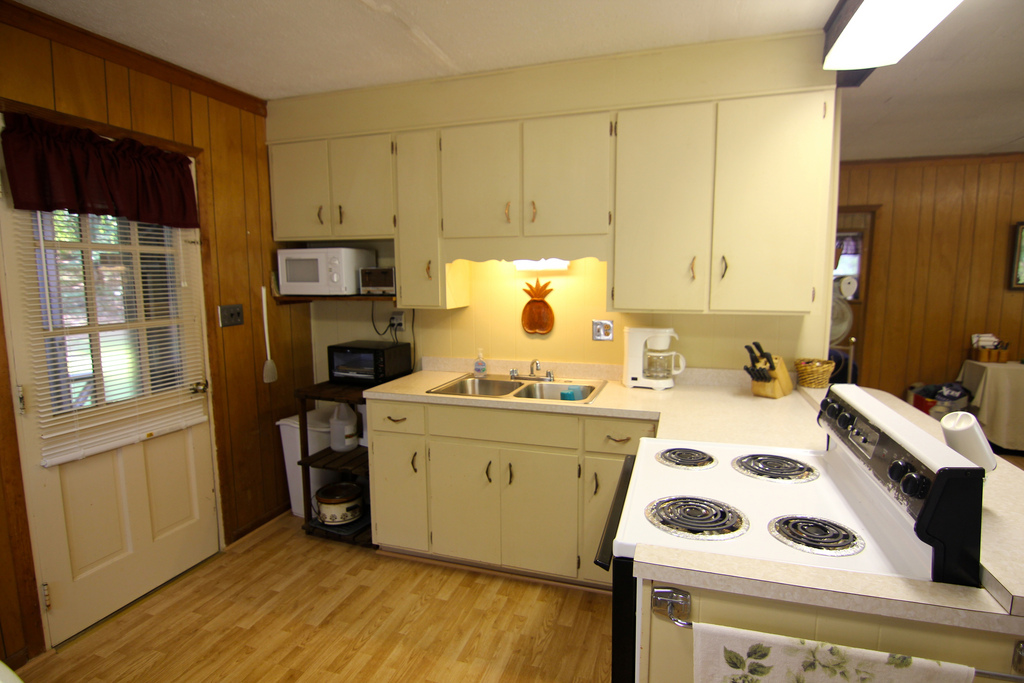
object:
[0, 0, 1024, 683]
kitchen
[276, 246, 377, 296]
microwave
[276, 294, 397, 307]
shelf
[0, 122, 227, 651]
door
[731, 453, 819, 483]
burner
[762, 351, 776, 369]
knives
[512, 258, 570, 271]
light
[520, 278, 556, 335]
ceramic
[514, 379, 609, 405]
sink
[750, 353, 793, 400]
block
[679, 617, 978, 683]
towel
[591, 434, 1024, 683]
oven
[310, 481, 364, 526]
crockpot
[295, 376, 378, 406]
shelf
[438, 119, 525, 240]
cabinet door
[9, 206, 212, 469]
blinds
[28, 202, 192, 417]
window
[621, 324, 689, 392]
coffee pot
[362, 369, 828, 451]
counter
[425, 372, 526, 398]
sink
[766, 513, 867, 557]
stove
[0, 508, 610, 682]
ground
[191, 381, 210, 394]
knob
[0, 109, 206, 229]
valance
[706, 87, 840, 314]
cabinet door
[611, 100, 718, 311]
cabinet door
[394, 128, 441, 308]
cabinet door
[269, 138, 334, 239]
cabinet door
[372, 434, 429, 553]
cabinet door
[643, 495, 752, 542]
burner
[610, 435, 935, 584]
stovetop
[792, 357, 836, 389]
basket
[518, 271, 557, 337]
pineapple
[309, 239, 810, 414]
wall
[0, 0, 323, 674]
wall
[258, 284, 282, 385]
flyswatter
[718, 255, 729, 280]
handle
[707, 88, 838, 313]
kitchen cabinet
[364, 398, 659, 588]
cabinets